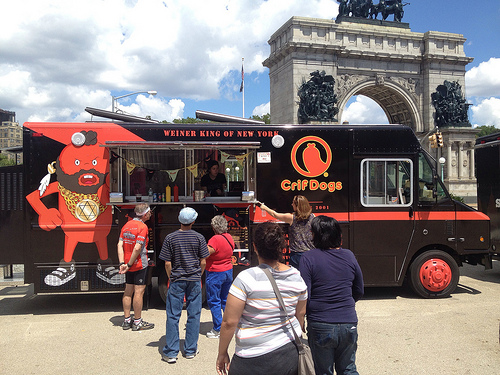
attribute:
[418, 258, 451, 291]
rim — Red 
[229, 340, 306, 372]
gray pants — Gray 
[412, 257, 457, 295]
hub caps — painted , red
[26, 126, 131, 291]
caricature — Mr. T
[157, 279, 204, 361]
blue jeans — Blue 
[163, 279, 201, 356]
jeans — blue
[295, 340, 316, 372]
handbag — gray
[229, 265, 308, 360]
shirt — striped, gray, white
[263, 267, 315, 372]
bag — Gray 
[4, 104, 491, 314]
food truck — parked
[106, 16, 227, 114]
clouds — white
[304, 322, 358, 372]
jeans — Dark 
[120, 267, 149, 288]
shorts — Black 